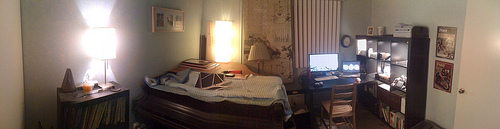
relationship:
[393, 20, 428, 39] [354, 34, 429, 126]
white printer on top of bookshelf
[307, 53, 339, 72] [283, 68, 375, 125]
computer on desk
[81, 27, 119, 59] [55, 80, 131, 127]
light on top of bookcase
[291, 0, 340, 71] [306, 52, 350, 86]
wall behind computer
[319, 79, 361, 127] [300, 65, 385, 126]
chair under desk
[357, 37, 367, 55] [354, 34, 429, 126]
light shining on bookshelf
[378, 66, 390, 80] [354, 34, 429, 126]
light shining on bookshelf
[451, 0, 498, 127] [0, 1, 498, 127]
door inside room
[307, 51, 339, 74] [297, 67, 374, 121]
computer on desk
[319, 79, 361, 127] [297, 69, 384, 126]
chair in front of desk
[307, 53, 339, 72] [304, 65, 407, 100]
computer on desk